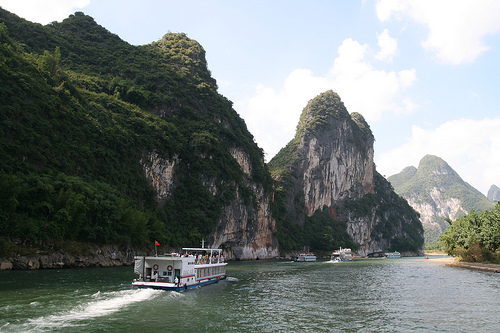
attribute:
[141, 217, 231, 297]
boat — long, wet, is cloudy, close, here, white, outdoors, large, big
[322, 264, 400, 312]
water — still, calm, close, here, green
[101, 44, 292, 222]
mountain — tall, close, here, large, massive, green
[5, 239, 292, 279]
shoreline — very rocky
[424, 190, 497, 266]
trees — are lush, are green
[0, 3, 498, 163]
sky — is light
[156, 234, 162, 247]
flag — is red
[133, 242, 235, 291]
boat — is white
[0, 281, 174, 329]
waves — are white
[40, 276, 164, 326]
water — is white